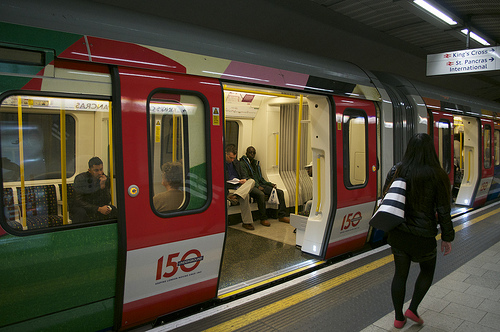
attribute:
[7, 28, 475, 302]
train — subway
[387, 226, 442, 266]
skirt — black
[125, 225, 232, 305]
numbers — red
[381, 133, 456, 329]
woman — brown, walking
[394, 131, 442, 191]
hair — long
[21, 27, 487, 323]
train — white, red, subway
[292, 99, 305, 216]
hand rail — yellow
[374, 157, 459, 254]
coat — black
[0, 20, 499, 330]
train — subway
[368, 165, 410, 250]
purse — black, white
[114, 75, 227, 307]
door — white, red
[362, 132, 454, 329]
female — walking away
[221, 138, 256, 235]
person — sitting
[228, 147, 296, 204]
man — sitting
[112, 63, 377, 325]
doors — open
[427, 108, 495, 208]
door — open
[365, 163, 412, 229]
bag — white, black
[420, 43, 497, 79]
sign — white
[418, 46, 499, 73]
sign — directional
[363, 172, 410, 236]
bag — black, white, striped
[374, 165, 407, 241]
bag — over-sized, striped, black, white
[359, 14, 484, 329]
station — subway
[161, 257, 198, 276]
numbers — red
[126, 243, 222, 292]
background — white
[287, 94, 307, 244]
bars — yellow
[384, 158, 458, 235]
jacket — black